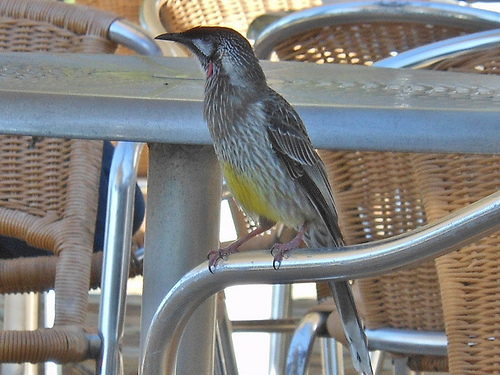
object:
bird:
[152, 25, 345, 274]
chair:
[361, 29, 499, 375]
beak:
[153, 31, 184, 43]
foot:
[270, 242, 285, 270]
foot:
[206, 247, 240, 274]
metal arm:
[140, 190, 499, 374]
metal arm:
[97, 20, 163, 340]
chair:
[0, 0, 161, 375]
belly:
[204, 104, 316, 227]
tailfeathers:
[313, 241, 376, 375]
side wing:
[263, 93, 346, 251]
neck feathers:
[200, 63, 266, 139]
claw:
[207, 265, 214, 275]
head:
[152, 24, 265, 87]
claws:
[273, 258, 277, 271]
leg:
[233, 220, 277, 251]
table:
[0, 48, 500, 154]